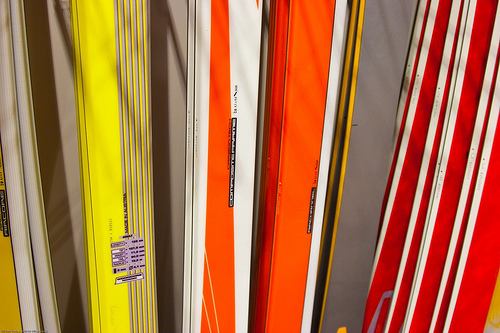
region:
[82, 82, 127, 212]
Yellow stripe on wall.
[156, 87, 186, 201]
Gray stripe on wall.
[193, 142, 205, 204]
White stripe on wall.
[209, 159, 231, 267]
Orange stripe on wall.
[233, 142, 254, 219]
White stripe on wall.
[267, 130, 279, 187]
Red stripe on wall.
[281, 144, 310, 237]
Orange stripe on wall.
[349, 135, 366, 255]
Gray stripe on wall.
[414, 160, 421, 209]
White stripe on wall.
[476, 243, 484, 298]
Red stripe on wall.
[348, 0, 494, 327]
Red Vertical blinds on display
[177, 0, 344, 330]
Orange vertical blinds on display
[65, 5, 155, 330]
Yellow vertical blinds on display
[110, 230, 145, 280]
Information label for vertical blinds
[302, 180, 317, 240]
Vertical blind manufacturer information label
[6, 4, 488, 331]
Multicolored vertical blinds on display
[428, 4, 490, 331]
White connector sheath for vertical blind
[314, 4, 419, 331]
Grey vertical blinds on display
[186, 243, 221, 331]
Draw string for vertical blinds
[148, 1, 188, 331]
Shadow of vertical blind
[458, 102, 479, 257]
the line is white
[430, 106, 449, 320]
the line is white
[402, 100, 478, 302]
the line is white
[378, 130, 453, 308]
the line is white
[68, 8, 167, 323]
the board is yellow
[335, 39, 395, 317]
a thin gray board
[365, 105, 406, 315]
a thin gray board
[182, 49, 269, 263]
a red and orange board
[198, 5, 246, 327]
a red and orange board